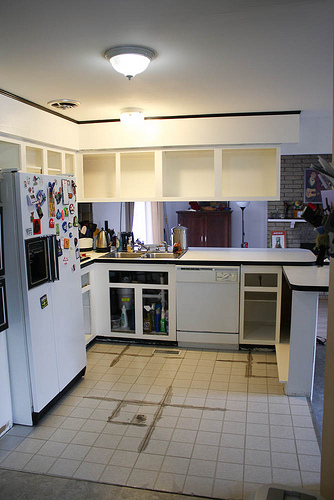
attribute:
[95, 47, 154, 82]
lamp — tall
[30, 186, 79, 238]
magnets — colorful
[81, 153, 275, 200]
cabinet — brown, wooden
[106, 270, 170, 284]
drawers — white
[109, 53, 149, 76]
bulb — bright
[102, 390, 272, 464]
floor tiles — lined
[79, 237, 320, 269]
countertop — white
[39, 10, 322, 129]
ceiling — white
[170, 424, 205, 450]
fllor tile — small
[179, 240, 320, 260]
counter — white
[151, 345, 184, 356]
vent — small, white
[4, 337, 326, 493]
floor — white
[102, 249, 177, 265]
double sink — silver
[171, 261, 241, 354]
dishwasher — white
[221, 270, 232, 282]
knob — simple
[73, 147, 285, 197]
cabinets — tall, white, empty, brightly lit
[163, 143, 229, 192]
square — white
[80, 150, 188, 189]
square — white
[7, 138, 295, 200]
shelves — open, white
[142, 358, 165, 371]
tile — white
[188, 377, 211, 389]
tile — white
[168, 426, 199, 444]
tile — white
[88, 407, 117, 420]
tile — white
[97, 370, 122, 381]
tile — white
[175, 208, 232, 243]
cabinet — brown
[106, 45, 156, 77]
fixture — brass colored, round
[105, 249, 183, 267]
kitchen sink — stainless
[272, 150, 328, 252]
wall — brick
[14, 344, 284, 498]
tile — small, white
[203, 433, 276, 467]
tiles — clean, square, white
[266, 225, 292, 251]
artwork poster — red, white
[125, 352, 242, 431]
floor tile — small, white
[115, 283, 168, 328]
cleaning — under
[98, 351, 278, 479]
tile — white, small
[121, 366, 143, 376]
tile — small, white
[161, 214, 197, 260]
canister — shiny, metal, round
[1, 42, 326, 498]
kitchen — open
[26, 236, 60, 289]
drink station — black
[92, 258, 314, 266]
side — black